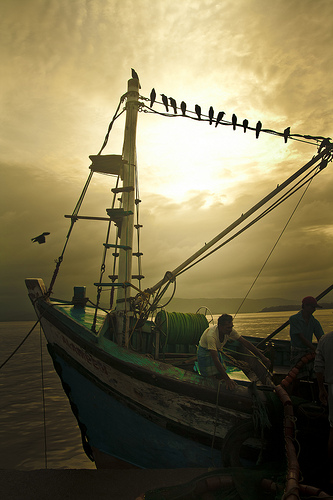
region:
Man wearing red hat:
[276, 291, 323, 366]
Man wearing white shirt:
[190, 313, 260, 390]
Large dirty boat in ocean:
[27, 72, 331, 466]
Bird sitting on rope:
[147, 85, 157, 109]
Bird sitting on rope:
[157, 90, 169, 112]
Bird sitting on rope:
[169, 94, 177, 115]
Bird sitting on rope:
[180, 98, 187, 116]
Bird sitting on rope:
[193, 101, 202, 123]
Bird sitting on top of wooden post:
[130, 65, 141, 92]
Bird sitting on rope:
[282, 121, 292, 149]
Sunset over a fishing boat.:
[78, 9, 330, 351]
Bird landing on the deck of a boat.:
[4, 193, 130, 360]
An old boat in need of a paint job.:
[26, 267, 262, 498]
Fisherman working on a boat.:
[190, 297, 330, 407]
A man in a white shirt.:
[199, 302, 263, 385]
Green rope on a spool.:
[155, 290, 221, 368]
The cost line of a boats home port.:
[174, 274, 330, 342]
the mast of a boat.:
[83, 63, 163, 308]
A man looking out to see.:
[280, 291, 331, 384]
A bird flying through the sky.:
[10, 198, 98, 301]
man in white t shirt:
[190, 312, 273, 393]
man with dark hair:
[191, 311, 272, 394]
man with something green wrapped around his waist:
[193, 311, 275, 390]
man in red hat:
[286, 294, 324, 358]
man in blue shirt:
[285, 295, 324, 360]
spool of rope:
[152, 301, 215, 366]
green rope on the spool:
[154, 309, 209, 350]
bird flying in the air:
[28, 226, 52, 248]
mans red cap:
[300, 294, 323, 311]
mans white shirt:
[197, 322, 241, 355]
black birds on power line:
[133, 87, 301, 153]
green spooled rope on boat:
[150, 313, 220, 360]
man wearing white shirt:
[194, 320, 262, 380]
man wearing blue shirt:
[278, 303, 326, 352]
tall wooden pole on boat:
[103, 199, 156, 357]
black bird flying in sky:
[24, 227, 56, 255]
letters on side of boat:
[52, 334, 163, 396]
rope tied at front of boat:
[63, 284, 100, 314]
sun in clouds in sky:
[148, 193, 274, 215]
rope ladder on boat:
[103, 203, 148, 328]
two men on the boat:
[195, 294, 319, 399]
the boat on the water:
[20, 269, 331, 495]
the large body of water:
[4, 304, 331, 487]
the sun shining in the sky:
[89, 65, 309, 213]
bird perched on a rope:
[124, 66, 295, 139]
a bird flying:
[27, 226, 53, 245]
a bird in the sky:
[25, 229, 54, 245]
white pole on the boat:
[110, 72, 139, 348]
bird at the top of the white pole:
[127, 62, 142, 88]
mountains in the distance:
[6, 283, 327, 312]